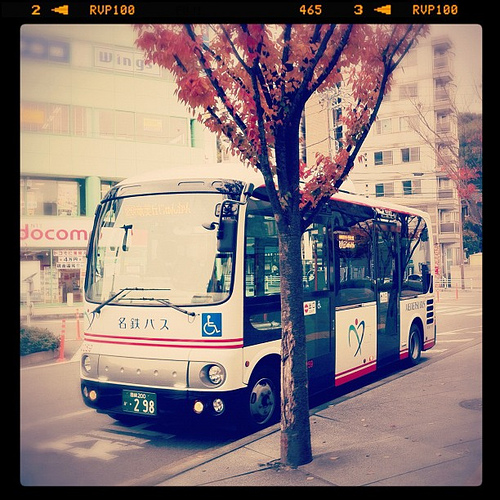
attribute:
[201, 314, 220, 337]
sign — handicap, blue, lbue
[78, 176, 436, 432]
bus — white, open, gray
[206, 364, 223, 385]
headlight — on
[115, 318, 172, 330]
text — blue, japanese, red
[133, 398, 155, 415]
number — 298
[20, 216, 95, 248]
sign — white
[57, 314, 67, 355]
cone — yellow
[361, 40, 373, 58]
leaf — red, orange